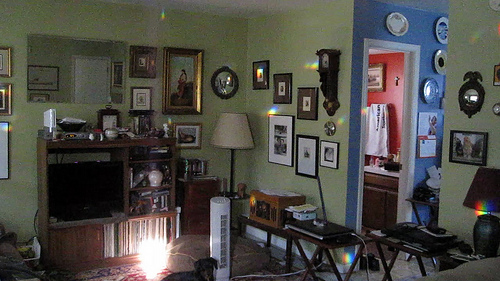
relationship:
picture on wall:
[251, 61, 270, 92] [220, 14, 350, 48]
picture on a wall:
[272, 69, 291, 106] [220, 14, 350, 48]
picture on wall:
[295, 85, 319, 122] [220, 14, 350, 48]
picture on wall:
[161, 45, 203, 114] [2, 5, 247, 245]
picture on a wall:
[320, 139, 340, 169] [220, 14, 350, 48]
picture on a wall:
[130, 84, 152, 115] [2, 5, 247, 245]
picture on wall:
[174, 121, 202, 149] [2, 5, 247, 245]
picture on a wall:
[297, 134, 320, 177] [220, 14, 350, 48]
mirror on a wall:
[25, 33, 126, 104] [2, 5, 247, 245]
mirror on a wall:
[458, 71, 484, 118] [437, 3, 497, 248]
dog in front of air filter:
[162, 256, 218, 280] [209, 195, 231, 278]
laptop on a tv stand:
[289, 216, 354, 241] [283, 227, 368, 278]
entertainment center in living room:
[36, 129, 180, 270] [0, 5, 498, 278]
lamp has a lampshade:
[210, 110, 254, 198] [211, 111, 253, 149]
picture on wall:
[449, 130, 489, 167] [437, 3, 497, 248]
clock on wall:
[316, 49, 342, 118] [220, 14, 350, 48]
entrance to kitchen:
[351, 5, 450, 251] [378, 46, 437, 179]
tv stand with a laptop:
[283, 227, 368, 278] [289, 216, 354, 241]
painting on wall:
[2, 46, 12, 77] [2, 5, 247, 245]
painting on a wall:
[2, 46, 12, 77] [2, 5, 247, 245]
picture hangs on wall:
[129, 44, 158, 78] [2, 5, 247, 245]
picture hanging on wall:
[449, 130, 489, 167] [437, 3, 497, 248]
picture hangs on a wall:
[272, 69, 291, 106] [220, 14, 350, 48]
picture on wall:
[272, 69, 291, 106] [220, 14, 350, 48]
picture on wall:
[267, 113, 294, 168] [220, 14, 350, 48]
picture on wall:
[297, 134, 320, 177] [220, 14, 350, 48]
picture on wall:
[320, 139, 340, 169] [220, 14, 350, 48]